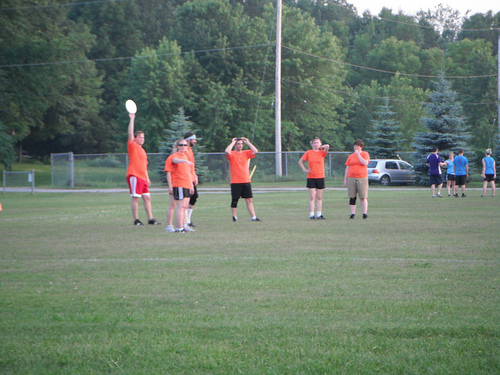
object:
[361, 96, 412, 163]
pine tree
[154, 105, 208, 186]
pine tree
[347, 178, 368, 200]
brown shorts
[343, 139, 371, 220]
person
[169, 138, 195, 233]
player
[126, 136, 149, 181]
shirt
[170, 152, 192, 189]
shirt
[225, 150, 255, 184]
shirt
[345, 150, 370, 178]
shirt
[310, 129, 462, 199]
parking lot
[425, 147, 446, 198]
man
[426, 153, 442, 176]
purple shirt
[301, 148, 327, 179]
orange shirt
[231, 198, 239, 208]
brace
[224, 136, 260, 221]
man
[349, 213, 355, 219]
shoe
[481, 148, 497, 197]
boy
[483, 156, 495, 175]
blue shirt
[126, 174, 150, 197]
short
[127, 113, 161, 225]
man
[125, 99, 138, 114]
frisbee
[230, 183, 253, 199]
shorts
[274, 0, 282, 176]
nails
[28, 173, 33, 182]
sign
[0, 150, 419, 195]
fence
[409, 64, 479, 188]
blue spruce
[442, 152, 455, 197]
person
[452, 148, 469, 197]
person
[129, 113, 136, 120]
hand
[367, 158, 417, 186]
car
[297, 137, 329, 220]
girl